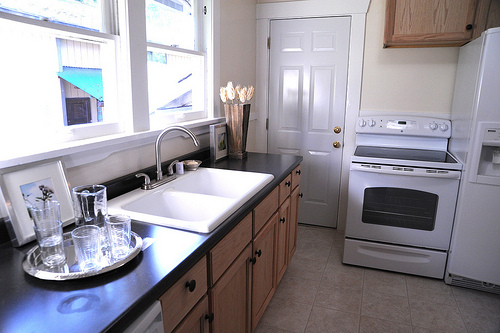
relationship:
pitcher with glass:
[72, 182, 109, 233] [103, 208, 135, 257]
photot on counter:
[0, 152, 82, 250] [1, 140, 303, 328]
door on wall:
[267, 15, 353, 231] [255, 1, 459, 236]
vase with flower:
[223, 102, 251, 159] [225, 77, 237, 102]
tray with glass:
[18, 224, 145, 285] [103, 208, 135, 257]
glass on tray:
[103, 208, 135, 257] [18, 224, 145, 285]